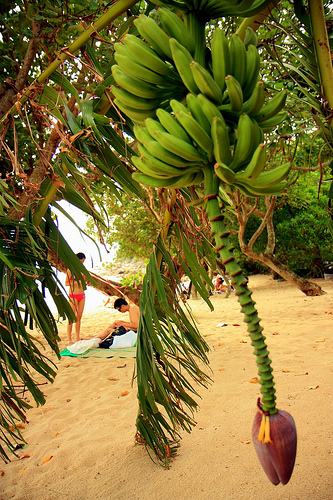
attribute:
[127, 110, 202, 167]
banana — green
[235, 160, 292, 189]
banana — green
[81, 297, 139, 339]
guy — one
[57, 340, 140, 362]
blanket — green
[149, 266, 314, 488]
leaves — green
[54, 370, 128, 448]
groves sand — small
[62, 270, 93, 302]
bikini — red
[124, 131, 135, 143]
sky — bright, clear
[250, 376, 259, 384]
groves — small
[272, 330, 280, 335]
groves — small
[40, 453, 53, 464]
groves — small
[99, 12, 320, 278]
tree — green, banana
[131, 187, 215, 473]
banana leaf — big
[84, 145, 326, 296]
tree — brown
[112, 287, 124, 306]
hair — short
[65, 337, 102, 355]
towel — blue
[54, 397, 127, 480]
beach — sandy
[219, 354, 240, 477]
groves — small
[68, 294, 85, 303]
bikini — red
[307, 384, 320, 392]
leaves — Dead 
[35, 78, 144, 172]
leaves — brown 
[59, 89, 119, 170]
leaves — green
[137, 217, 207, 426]
leaves — green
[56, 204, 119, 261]
light — day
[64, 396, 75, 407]
grove — small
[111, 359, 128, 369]
grove — small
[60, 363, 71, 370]
grove — small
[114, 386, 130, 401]
grove — small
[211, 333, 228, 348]
grove — small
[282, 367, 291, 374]
groves — small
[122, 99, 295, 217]
bananas — green